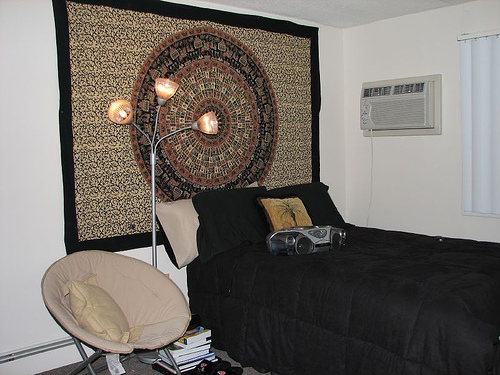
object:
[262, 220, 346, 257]
radio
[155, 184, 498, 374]
bed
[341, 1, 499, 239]
wall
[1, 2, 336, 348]
wall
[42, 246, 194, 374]
chair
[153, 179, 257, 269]
pillow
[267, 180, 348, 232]
pillow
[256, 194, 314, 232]
pillow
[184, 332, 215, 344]
books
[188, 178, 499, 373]
bedding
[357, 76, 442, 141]
air conditioner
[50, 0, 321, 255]
rug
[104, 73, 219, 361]
lamp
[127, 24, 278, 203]
design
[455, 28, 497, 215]
blinds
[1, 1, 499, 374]
bedroom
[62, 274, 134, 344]
pillow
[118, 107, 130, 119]
bulb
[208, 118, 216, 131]
bulb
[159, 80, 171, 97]
bulb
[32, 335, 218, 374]
floor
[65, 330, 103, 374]
legs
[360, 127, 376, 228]
cord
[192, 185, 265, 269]
pillows